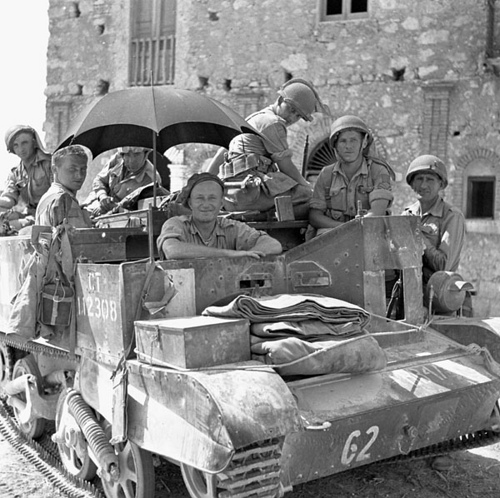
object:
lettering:
[342, 425, 380, 465]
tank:
[0, 196, 499, 497]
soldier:
[308, 117, 392, 230]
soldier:
[155, 175, 283, 258]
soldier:
[397, 152, 465, 272]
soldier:
[33, 146, 96, 226]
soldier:
[213, 80, 318, 216]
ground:
[1, 436, 499, 497]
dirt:
[288, 448, 499, 497]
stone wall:
[46, 3, 499, 321]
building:
[44, 1, 499, 321]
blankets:
[202, 295, 371, 340]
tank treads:
[1, 333, 277, 497]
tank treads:
[369, 409, 499, 468]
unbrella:
[53, 86, 269, 160]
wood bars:
[134, 38, 140, 88]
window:
[123, 0, 174, 91]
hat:
[177, 173, 224, 206]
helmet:
[406, 155, 448, 187]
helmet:
[329, 114, 374, 149]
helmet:
[275, 82, 313, 124]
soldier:
[1, 120, 55, 235]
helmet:
[2, 121, 35, 153]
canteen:
[38, 277, 72, 326]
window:
[463, 174, 494, 221]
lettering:
[76, 273, 118, 322]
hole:
[390, 68, 408, 82]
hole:
[221, 77, 233, 91]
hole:
[197, 75, 210, 89]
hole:
[96, 81, 109, 94]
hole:
[208, 10, 221, 21]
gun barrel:
[386, 280, 402, 321]